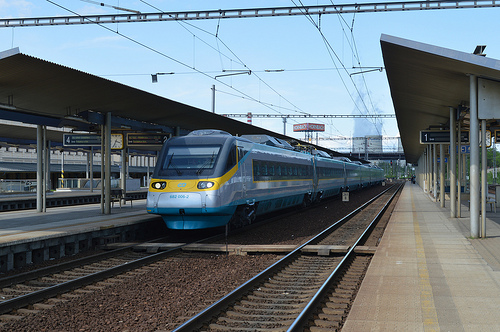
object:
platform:
[0, 46, 373, 253]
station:
[0, 0, 499, 331]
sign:
[119, 129, 174, 148]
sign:
[417, 126, 476, 144]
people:
[408, 173, 417, 185]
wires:
[43, 0, 413, 139]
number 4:
[65, 135, 75, 145]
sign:
[63, 132, 102, 147]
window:
[159, 142, 221, 177]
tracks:
[0, 225, 222, 313]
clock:
[109, 132, 125, 150]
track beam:
[106, 237, 375, 254]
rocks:
[0, 179, 404, 332]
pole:
[58, 153, 65, 190]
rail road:
[166, 178, 407, 331]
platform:
[333, 34, 499, 332]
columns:
[464, 76, 479, 238]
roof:
[379, 25, 499, 167]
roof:
[0, 43, 376, 166]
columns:
[31, 113, 45, 216]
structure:
[218, 110, 395, 127]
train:
[141, 128, 386, 234]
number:
[161, 134, 170, 143]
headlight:
[196, 179, 214, 191]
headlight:
[149, 181, 168, 189]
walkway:
[341, 180, 499, 332]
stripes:
[53, 176, 75, 191]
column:
[105, 109, 113, 214]